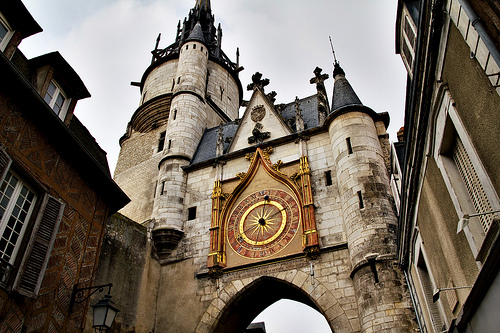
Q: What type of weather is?
A: It is clear.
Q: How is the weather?
A: It is clear.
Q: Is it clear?
A: Yes, it is clear.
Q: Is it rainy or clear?
A: It is clear.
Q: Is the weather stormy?
A: No, it is clear.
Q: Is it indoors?
A: Yes, it is indoors.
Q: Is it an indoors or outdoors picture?
A: It is indoors.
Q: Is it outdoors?
A: No, it is indoors.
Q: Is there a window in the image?
A: Yes, there is a window.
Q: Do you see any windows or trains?
A: Yes, there is a window.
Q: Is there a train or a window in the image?
A: Yes, there is a window.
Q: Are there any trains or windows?
A: Yes, there is a window.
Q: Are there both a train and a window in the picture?
A: No, there is a window but no trains.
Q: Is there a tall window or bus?
A: Yes, there is a tall window.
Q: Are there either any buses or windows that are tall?
A: Yes, the window is tall.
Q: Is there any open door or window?
A: Yes, there is an open window.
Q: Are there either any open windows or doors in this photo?
A: Yes, there is an open window.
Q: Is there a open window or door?
A: Yes, there is an open window.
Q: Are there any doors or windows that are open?
A: Yes, the window is open.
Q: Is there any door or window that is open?
A: Yes, the window is open.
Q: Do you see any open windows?
A: Yes, there is an open window.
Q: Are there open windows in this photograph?
A: Yes, there is an open window.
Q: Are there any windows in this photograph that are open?
A: Yes, there is a window that is open.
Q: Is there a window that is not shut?
A: Yes, there is a open window.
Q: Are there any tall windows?
A: Yes, there is a tall window.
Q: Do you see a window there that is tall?
A: Yes, there is a window that is tall.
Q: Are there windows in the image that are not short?
A: Yes, there is a tall window.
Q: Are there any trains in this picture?
A: No, there are no trains.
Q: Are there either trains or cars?
A: No, there are no trains or cars.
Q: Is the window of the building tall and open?
A: Yes, the window is tall and open.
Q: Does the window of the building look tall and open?
A: Yes, the window is tall and open.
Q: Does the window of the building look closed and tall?
A: No, the window is tall but open.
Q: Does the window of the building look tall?
A: Yes, the window is tall.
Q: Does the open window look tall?
A: Yes, the window is tall.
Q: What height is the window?
A: The window is tall.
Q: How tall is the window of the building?
A: The window is tall.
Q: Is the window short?
A: No, the window is tall.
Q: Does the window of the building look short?
A: No, the window is tall.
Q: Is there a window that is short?
A: No, there is a window but it is tall.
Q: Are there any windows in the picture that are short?
A: No, there is a window but it is tall.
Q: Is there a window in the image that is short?
A: No, there is a window but it is tall.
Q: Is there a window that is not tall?
A: No, there is a window but it is tall.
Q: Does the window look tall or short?
A: The window is tall.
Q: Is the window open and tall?
A: Yes, the window is open and tall.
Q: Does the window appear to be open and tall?
A: Yes, the window is open and tall.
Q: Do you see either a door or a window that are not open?
A: No, there is a window but it is open.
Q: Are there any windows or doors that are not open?
A: No, there is a window but it is open.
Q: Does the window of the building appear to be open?
A: Yes, the window is open.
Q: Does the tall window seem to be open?
A: Yes, the window is open.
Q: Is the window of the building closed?
A: No, the window is open.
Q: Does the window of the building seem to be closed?
A: No, the window is open.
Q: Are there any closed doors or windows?
A: No, there is a window but it is open.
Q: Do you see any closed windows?
A: No, there is a window but it is open.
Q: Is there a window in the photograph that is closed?
A: No, there is a window but it is open.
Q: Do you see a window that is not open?
A: No, there is a window but it is open.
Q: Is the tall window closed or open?
A: The window is open.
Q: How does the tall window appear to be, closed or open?
A: The window is open.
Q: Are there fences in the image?
A: No, there are no fences.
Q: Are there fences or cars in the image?
A: No, there are no fences or cars.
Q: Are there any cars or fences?
A: No, there are no fences or cars.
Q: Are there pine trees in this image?
A: No, there are no pine trees.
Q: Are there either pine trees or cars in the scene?
A: No, there are no pine trees or cars.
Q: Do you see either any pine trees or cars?
A: No, there are no pine trees or cars.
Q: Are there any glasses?
A: No, there are no glasses.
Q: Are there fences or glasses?
A: No, there are no glasses or fences.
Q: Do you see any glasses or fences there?
A: No, there are no glasses or fences.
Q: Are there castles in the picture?
A: Yes, there is a castle.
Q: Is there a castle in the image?
A: Yes, there is a castle.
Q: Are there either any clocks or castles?
A: Yes, there is a castle.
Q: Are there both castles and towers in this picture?
A: Yes, there are both a castle and a tower.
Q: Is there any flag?
A: No, there are no flags.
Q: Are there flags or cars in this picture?
A: No, there are no flags or cars.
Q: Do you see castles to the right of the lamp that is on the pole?
A: Yes, there is a castle to the right of the lamp.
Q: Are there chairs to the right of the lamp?
A: No, there is a castle to the right of the lamp.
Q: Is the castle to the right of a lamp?
A: Yes, the castle is to the right of a lamp.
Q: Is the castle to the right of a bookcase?
A: No, the castle is to the right of a lamp.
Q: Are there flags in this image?
A: No, there are no flags.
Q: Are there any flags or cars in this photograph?
A: No, there are no flags or cars.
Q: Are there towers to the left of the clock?
A: Yes, there is a tower to the left of the clock.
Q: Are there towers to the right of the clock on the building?
A: No, the tower is to the left of the clock.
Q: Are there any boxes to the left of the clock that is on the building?
A: No, there is a tower to the left of the clock.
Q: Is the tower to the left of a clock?
A: Yes, the tower is to the left of a clock.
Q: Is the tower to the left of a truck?
A: No, the tower is to the left of a clock.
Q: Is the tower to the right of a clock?
A: No, the tower is to the left of a clock.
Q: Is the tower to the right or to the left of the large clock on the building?
A: The tower is to the left of the clock.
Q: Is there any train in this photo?
A: No, there are no trains.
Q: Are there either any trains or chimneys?
A: No, there are no trains or chimneys.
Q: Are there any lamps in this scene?
A: Yes, there is a lamp.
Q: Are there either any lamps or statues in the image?
A: Yes, there is a lamp.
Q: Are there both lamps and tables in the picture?
A: No, there is a lamp but no tables.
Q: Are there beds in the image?
A: No, there are no beds.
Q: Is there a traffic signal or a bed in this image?
A: No, there are no beds or traffic lights.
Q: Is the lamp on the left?
A: Yes, the lamp is on the left of the image.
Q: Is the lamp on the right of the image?
A: No, the lamp is on the left of the image.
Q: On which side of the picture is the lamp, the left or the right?
A: The lamp is on the left of the image.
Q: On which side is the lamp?
A: The lamp is on the left of the image.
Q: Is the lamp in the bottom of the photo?
A: Yes, the lamp is in the bottom of the image.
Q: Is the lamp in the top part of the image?
A: No, the lamp is in the bottom of the image.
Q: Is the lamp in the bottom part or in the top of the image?
A: The lamp is in the bottom of the image.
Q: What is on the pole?
A: The lamp is on the pole.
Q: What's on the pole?
A: The lamp is on the pole.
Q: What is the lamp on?
A: The lamp is on the pole.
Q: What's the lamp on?
A: The lamp is on the pole.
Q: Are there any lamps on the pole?
A: Yes, there is a lamp on the pole.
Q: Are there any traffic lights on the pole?
A: No, there is a lamp on the pole.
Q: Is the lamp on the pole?
A: Yes, the lamp is on the pole.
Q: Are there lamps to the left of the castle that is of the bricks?
A: Yes, there is a lamp to the left of the castle.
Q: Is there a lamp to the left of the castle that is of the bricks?
A: Yes, there is a lamp to the left of the castle.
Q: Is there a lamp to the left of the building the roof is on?
A: Yes, there is a lamp to the left of the castle.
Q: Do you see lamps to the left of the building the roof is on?
A: Yes, there is a lamp to the left of the castle.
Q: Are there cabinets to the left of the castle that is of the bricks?
A: No, there is a lamp to the left of the castle.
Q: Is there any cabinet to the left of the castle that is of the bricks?
A: No, there is a lamp to the left of the castle.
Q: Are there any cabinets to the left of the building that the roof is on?
A: No, there is a lamp to the left of the castle.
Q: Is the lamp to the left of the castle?
A: Yes, the lamp is to the left of the castle.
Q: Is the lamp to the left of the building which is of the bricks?
A: Yes, the lamp is to the left of the castle.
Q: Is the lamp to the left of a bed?
A: No, the lamp is to the left of the castle.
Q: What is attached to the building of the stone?
A: The lamp is attached to the building.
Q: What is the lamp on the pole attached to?
A: The lamp is attached to the building.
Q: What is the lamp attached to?
A: The lamp is attached to the building.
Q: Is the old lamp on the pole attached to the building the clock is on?
A: Yes, the lamp is attached to the building.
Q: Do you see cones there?
A: No, there are no cones.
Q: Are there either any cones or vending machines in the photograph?
A: No, there are no cones or vending machines.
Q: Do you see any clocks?
A: Yes, there is a clock.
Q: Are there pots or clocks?
A: Yes, there is a clock.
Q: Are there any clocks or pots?
A: Yes, there is a clock.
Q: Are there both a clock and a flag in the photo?
A: No, there is a clock but no flags.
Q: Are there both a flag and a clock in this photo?
A: No, there is a clock but no flags.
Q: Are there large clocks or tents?
A: Yes, there is a large clock.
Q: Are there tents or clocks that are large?
A: Yes, the clock is large.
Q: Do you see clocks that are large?
A: Yes, there is a large clock.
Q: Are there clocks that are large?
A: Yes, there is a clock that is large.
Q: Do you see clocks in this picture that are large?
A: Yes, there is a clock that is large.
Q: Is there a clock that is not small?
A: Yes, there is a large clock.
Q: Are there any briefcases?
A: No, there are no briefcases.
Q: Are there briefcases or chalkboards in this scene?
A: No, there are no briefcases or chalkboards.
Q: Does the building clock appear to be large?
A: Yes, the clock is large.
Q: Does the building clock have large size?
A: Yes, the clock is large.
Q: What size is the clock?
A: The clock is large.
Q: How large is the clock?
A: The clock is large.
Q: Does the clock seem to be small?
A: No, the clock is large.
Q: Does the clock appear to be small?
A: No, the clock is large.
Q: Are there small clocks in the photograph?
A: No, there is a clock but it is large.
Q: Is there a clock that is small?
A: No, there is a clock but it is large.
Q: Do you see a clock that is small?
A: No, there is a clock but it is large.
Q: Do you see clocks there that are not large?
A: No, there is a clock but it is large.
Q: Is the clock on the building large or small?
A: The clock is large.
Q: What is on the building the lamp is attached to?
A: The clock is on the building.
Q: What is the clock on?
A: The clock is on the building.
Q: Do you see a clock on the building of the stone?
A: Yes, there is a clock on the building.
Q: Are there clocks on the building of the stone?
A: Yes, there is a clock on the building.